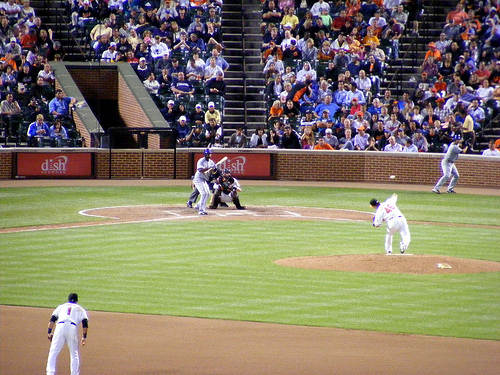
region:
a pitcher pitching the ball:
[358, 170, 419, 267]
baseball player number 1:
[37, 282, 97, 371]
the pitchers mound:
[286, 240, 496, 288]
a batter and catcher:
[187, 140, 246, 217]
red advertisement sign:
[15, 150, 97, 180]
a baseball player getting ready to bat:
[432, 123, 474, 196]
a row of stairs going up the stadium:
[212, 2, 280, 141]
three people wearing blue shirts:
[25, 86, 85, 146]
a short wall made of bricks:
[91, 140, 498, 187]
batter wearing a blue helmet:
[188, 143, 230, 188]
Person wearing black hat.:
[52, 285, 100, 317]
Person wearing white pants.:
[38, 317, 95, 365]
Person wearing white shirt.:
[46, 292, 118, 362]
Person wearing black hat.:
[360, 178, 373, 224]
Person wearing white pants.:
[376, 233, 423, 253]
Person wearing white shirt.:
[371, 194, 412, 229]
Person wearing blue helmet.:
[443, 127, 482, 172]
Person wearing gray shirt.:
[435, 123, 465, 199]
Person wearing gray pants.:
[422, 159, 464, 199]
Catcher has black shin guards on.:
[209, 185, 286, 227]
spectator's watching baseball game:
[8, 9, 483, 151]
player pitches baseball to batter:
[342, 166, 492, 284]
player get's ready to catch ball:
[416, 123, 487, 202]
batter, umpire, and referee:
[174, 143, 249, 230]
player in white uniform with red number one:
[39, 284, 116, 369]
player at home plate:
[73, 134, 308, 231]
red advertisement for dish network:
[17, 128, 112, 191]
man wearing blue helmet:
[170, 134, 237, 181]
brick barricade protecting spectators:
[10, 117, 497, 207]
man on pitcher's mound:
[331, 180, 450, 272]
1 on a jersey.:
[41, 294, 96, 343]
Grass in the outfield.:
[157, 337, 242, 363]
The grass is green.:
[191, 254, 254, 301]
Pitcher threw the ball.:
[346, 167, 444, 247]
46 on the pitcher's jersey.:
[372, 194, 408, 223]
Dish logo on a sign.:
[21, 156, 78, 179]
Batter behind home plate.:
[170, 149, 241, 204]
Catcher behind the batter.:
[204, 171, 249, 209]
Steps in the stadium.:
[218, 83, 275, 114]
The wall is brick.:
[303, 151, 355, 183]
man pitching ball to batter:
[172, 141, 492, 305]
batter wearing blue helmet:
[184, 144, 289, 241]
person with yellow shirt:
[197, 94, 244, 146]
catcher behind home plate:
[179, 133, 279, 210]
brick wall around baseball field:
[301, 132, 430, 242]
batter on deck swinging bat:
[399, 129, 486, 210]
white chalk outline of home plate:
[117, 160, 308, 228]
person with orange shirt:
[299, 116, 344, 155]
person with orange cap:
[342, 119, 379, 156]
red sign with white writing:
[17, 140, 153, 191]